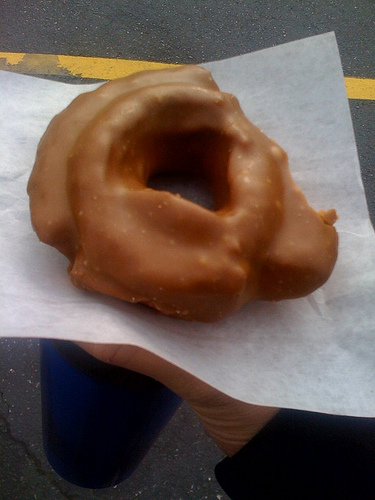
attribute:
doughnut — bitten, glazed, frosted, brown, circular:
[25, 63, 353, 347]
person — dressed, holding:
[31, 243, 374, 494]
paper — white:
[4, 46, 373, 412]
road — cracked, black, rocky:
[4, 0, 374, 134]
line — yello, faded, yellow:
[1, 49, 373, 109]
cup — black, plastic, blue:
[22, 320, 175, 494]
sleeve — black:
[197, 383, 374, 497]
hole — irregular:
[114, 121, 254, 218]